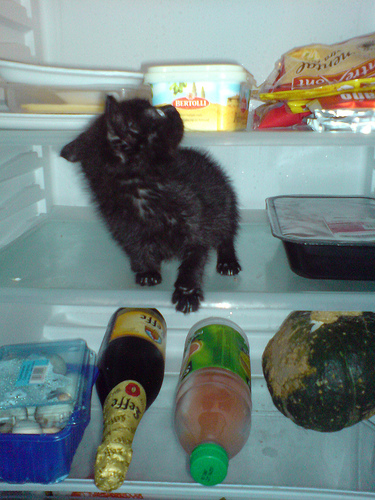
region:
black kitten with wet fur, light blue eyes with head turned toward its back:
[61, 95, 242, 314]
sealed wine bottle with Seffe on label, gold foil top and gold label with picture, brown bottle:
[94, 306, 163, 491]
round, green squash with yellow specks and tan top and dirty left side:
[262, 311, 372, 429]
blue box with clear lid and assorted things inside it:
[2, 339, 99, 484]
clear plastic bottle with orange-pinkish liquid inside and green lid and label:
[174, 317, 251, 486]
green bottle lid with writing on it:
[187, 441, 230, 487]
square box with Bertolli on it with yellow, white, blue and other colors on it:
[142, 64, 256, 130]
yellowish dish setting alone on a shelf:
[20, 103, 105, 114]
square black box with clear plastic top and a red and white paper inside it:
[266, 194, 374, 280]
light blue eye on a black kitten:
[154, 107, 165, 117]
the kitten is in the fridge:
[51, 92, 250, 307]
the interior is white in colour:
[124, 19, 286, 209]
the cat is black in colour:
[63, 96, 241, 311]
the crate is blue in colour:
[14, 343, 92, 474]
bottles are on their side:
[113, 293, 245, 461]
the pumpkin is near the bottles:
[259, 306, 374, 452]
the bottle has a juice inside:
[178, 336, 254, 487]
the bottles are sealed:
[90, 322, 233, 496]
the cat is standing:
[67, 104, 229, 316]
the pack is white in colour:
[156, 53, 242, 133]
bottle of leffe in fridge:
[79, 309, 170, 484]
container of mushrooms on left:
[11, 337, 98, 495]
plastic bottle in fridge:
[163, 335, 235, 473]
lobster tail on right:
[251, 316, 357, 462]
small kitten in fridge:
[82, 103, 193, 232]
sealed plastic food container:
[254, 197, 369, 260]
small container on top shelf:
[157, 64, 241, 130]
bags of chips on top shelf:
[284, 35, 371, 126]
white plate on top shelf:
[12, 58, 132, 84]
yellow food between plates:
[17, 94, 152, 127]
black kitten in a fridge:
[58, 78, 253, 338]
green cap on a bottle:
[182, 434, 233, 495]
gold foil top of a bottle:
[94, 430, 124, 495]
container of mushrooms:
[2, 341, 89, 487]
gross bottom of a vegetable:
[274, 319, 371, 436]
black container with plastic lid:
[260, 173, 370, 296]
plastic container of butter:
[137, 58, 259, 140]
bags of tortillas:
[268, 43, 370, 131]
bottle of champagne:
[97, 304, 152, 497]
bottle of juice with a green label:
[177, 322, 259, 498]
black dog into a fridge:
[60, 88, 242, 315]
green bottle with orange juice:
[170, 315, 247, 481]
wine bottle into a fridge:
[90, 305, 168, 491]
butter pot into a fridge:
[148, 60, 254, 136]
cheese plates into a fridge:
[1, 57, 141, 125]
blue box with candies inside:
[1, 336, 99, 484]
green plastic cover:
[184, 442, 231, 487]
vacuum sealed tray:
[265, 193, 373, 280]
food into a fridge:
[2, 29, 373, 490]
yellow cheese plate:
[18, 97, 119, 115]